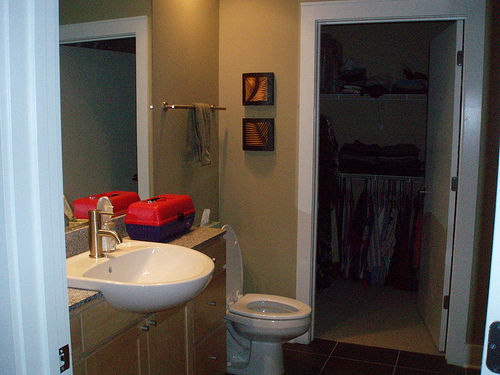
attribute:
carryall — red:
[120, 196, 195, 243]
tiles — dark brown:
[253, 326, 491, 373]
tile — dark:
[328, 341, 399, 366]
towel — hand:
[171, 90, 256, 135]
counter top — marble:
[63, 203, 228, 311]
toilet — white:
[225, 222, 312, 370]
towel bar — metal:
[160, 100, 228, 111]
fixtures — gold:
[88, 208, 122, 256]